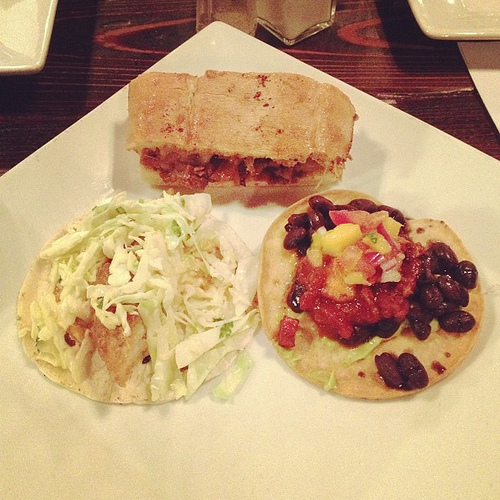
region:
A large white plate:
[11, 29, 491, 484]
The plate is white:
[29, 6, 490, 488]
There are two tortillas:
[0, 189, 477, 412]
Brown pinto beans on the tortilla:
[371, 239, 486, 379]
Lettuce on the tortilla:
[31, 190, 232, 387]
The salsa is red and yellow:
[253, 230, 426, 338]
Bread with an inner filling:
[103, 50, 380, 192]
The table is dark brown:
[46, 23, 457, 108]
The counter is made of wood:
[34, 10, 459, 98]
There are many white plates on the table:
[6, 3, 497, 387]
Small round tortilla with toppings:
[14, 189, 254, 408]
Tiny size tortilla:
[259, 185, 489, 405]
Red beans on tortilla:
[373, 351, 430, 391]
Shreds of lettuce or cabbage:
[99, 196, 206, 285]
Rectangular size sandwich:
[129, 71, 355, 191]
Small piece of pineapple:
[312, 220, 359, 258]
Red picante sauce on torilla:
[281, 218, 416, 343]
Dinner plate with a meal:
[0, 17, 495, 496]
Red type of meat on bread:
[141, 149, 334, 190]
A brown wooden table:
[1, 3, 496, 185]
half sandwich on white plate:
[127, 62, 362, 187]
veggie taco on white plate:
[264, 191, 489, 395]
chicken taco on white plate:
[16, 191, 248, 412]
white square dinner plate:
[1, 18, 498, 498]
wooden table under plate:
[0, 0, 499, 177]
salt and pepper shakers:
[193, 0, 341, 45]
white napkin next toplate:
[458, 42, 497, 134]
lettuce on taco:
[36, 187, 263, 403]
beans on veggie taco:
[286, 192, 476, 384]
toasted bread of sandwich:
[123, 67, 358, 157]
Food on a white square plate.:
[39, 83, 477, 405]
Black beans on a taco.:
[405, 237, 470, 362]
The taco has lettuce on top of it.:
[43, 206, 228, 378]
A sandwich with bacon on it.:
[95, 54, 386, 250]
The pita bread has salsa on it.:
[304, 215, 419, 338]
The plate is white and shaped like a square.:
[28, 190, 450, 488]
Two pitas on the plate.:
[38, 206, 471, 426]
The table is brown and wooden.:
[361, 51, 453, 116]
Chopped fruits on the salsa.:
[329, 210, 391, 272]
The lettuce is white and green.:
[126, 205, 239, 346]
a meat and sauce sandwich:
[114, 60, 359, 191]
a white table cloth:
[234, 415, 353, 497]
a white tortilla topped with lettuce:
[11, 207, 246, 402]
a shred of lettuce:
[215, 376, 247, 396]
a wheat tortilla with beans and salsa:
[247, 195, 494, 437]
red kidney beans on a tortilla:
[420, 257, 477, 332]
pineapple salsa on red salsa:
[303, 229, 393, 284]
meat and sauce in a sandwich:
[147, 150, 325, 188]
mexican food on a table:
[47, 83, 484, 430]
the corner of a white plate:
[181, 20, 292, 75]